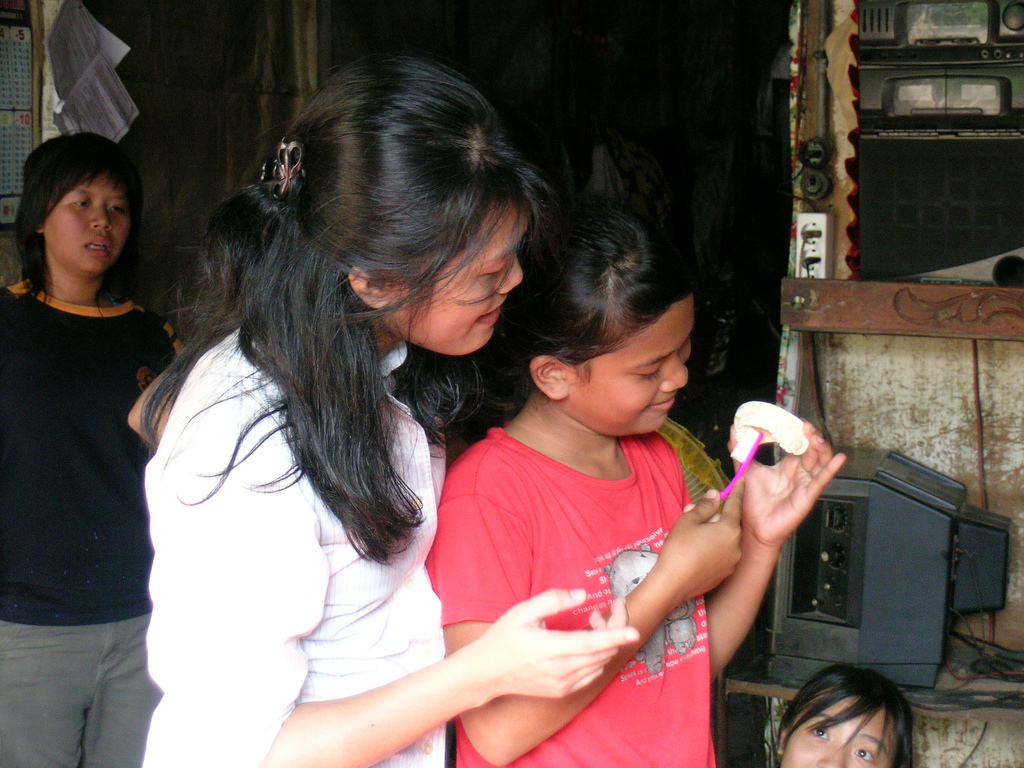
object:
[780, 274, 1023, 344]
shelf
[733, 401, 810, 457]
model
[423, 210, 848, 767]
aide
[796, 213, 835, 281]
power strip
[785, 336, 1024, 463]
wall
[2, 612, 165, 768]
pants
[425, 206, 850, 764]
child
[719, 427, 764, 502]
toothbrush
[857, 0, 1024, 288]
stereo system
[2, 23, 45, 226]
wall callender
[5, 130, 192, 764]
woman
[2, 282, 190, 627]
shirt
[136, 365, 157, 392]
accent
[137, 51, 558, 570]
hair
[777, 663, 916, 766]
hair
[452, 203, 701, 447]
hair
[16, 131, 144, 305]
hair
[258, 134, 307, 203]
hair clip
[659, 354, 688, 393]
nose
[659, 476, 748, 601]
hand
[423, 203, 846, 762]
person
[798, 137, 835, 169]
outlet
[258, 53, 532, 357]
head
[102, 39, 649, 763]
woman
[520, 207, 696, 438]
head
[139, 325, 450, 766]
shirt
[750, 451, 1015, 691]
television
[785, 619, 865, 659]
dust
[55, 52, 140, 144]
papers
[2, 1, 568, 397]
wall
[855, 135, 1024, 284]
speakers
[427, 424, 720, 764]
tee shirt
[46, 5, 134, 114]
paper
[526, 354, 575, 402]
ear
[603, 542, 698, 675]
bear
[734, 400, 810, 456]
teeth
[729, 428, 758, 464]
bristles